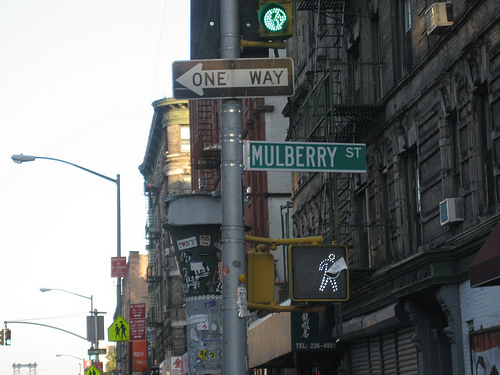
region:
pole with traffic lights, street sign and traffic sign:
[166, 6, 371, 369]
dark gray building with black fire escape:
[285, 10, 493, 369]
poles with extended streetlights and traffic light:
[0, 140, 122, 368]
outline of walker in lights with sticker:
[285, 236, 351, 301]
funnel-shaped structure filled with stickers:
[162, 190, 227, 371]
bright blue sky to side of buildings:
[5, 1, 190, 369]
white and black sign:
[170, 54, 289, 97]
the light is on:
[317, 254, 337, 289]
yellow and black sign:
[105, 316, 131, 340]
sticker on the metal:
[178, 234, 196, 249]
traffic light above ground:
[0, 326, 11, 346]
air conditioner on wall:
[440, 196, 462, 224]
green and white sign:
[247, 139, 366, 173]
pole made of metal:
[220, 1, 249, 373]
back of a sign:
[87, 316, 104, 339]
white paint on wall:
[458, 281, 498, 373]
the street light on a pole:
[0, 136, 135, 373]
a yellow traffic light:
[245, 227, 351, 326]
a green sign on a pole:
[241, 134, 373, 181]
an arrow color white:
[163, 50, 297, 107]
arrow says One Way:
[166, 52, 298, 106]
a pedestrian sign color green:
[97, 309, 139, 350]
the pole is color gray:
[206, 1, 260, 372]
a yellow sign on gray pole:
[228, 4, 302, 56]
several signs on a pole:
[102, 172, 151, 373]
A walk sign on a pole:
[283, 242, 347, 300]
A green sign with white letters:
[245, 140, 365, 174]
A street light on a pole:
[10, 150, 35, 164]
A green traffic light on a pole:
[255, 2, 293, 38]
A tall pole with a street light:
[108, 157, 127, 374]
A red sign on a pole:
[110, 254, 127, 277]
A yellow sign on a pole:
[104, 317, 131, 340]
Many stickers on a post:
[174, 227, 223, 373]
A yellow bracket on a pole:
[235, 229, 287, 306]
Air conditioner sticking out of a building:
[434, 195, 464, 226]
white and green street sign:
[240, 133, 365, 178]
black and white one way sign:
[168, 54, 293, 98]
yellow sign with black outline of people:
[109, 316, 130, 344]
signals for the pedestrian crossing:
[246, 227, 347, 317]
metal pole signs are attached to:
[213, 0, 251, 367]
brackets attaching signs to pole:
[215, 97, 243, 173]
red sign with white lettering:
[108, 252, 127, 277]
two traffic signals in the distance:
[0, 329, 14, 346]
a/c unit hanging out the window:
[436, 196, 460, 221]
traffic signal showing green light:
[239, 4, 296, 49]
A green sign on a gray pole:
[245, 140, 368, 173]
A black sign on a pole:
[171, 58, 298, 98]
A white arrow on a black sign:
[176, 65, 289, 91]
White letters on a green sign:
[250, 143, 364, 168]